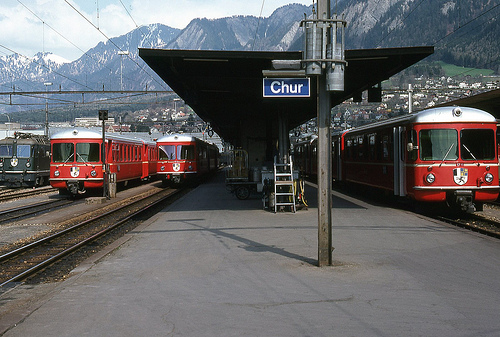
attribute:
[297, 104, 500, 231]
train — stopped, white, red, is dark, is green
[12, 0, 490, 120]
mountains — tall, white, big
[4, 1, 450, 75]
sky — white, huge, blue, is small, is white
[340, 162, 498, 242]
tracks — black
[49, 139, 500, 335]
pavement — blue, small, grey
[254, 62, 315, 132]
sign — blue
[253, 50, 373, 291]
pole — metal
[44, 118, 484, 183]
trains — bright red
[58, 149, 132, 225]
train top — silver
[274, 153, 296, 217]
ladder — is silver, is colored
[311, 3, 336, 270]
pole — is metal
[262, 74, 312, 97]
sign — is blue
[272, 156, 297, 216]
ladder — is grey